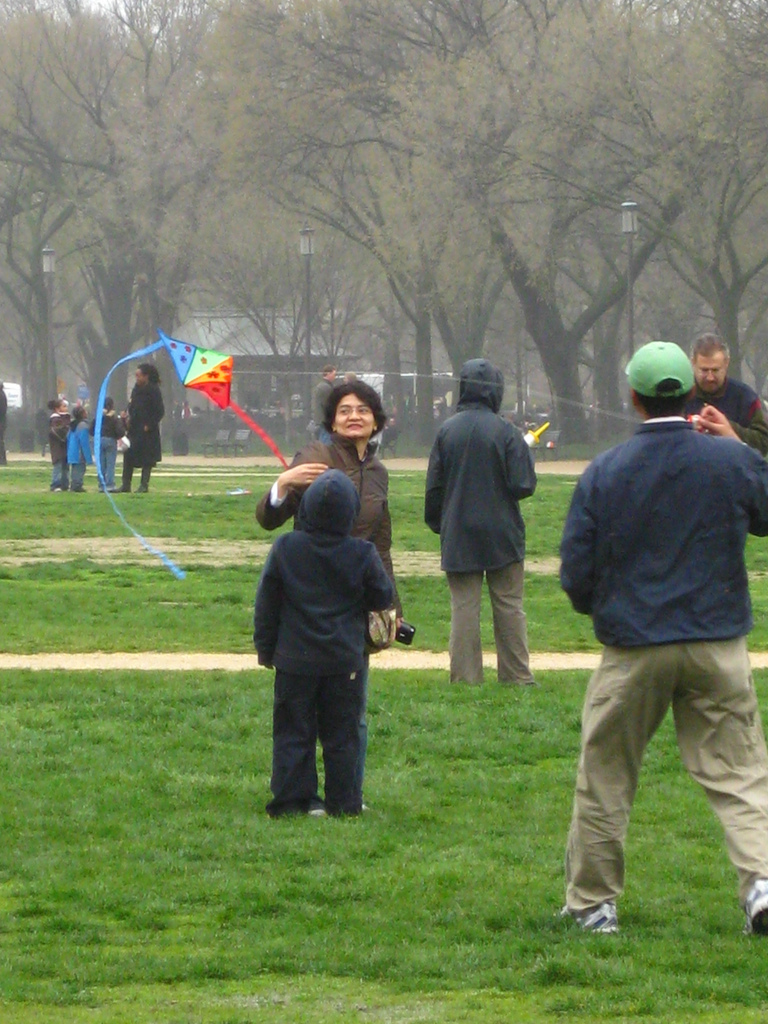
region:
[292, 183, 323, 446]
Tall street light in the park.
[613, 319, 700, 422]
Man wearing green ball cap.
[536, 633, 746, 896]
Man wearing tan pants.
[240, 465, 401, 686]
Young person wearing a blue jacket.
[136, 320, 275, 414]
A multi colored kite in the breeze.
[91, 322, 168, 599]
Bright blue tail of the kite.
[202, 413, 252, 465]
Bench across the park.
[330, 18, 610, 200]
Trees beginning to bud in the park.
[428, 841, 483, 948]
A person eating a orange.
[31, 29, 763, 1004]
people in a park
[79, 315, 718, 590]
kite on a string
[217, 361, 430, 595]
this is a woman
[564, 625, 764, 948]
man wearing khaki pants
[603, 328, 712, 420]
man wearing a green hat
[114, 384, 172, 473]
a black long coat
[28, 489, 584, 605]
a patch of dirt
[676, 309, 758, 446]
a man looking down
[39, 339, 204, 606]
tail of the kite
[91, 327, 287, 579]
a colorful kite flying in the air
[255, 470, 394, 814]
kid wearing a hooded jacket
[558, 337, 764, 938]
man with green cap flying a kite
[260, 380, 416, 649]
woman with brown hair holding a camera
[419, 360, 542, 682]
man wearing tan pants and a hooded raincoat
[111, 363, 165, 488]
woman wearing black raincoat with a black pony tail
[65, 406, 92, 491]
kid wearing a light blue coat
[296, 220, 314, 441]
a white streetlamp on a black metal pole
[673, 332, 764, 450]
man wearing a green and blue jacket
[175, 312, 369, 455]
a house behind a metal fence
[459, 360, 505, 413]
tan person has a head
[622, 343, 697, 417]
tan person has a head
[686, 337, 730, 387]
tan person has a head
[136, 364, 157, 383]
tan person has a head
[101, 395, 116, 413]
tan person has a head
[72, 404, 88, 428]
tan person has a head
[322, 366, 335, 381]
tan person has a head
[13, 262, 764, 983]
a group of people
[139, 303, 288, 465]
a multicolored low kite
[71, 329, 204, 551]
tail of the kite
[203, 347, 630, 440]
string on the kite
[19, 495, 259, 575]
patch on the dirt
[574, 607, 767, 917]
pair of khaki pants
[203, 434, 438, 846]
child in the grass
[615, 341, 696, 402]
a green baseball hat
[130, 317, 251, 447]
kite is in the air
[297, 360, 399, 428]
woman has black hair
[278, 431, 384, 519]
woman is wearing a jacket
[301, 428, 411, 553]
jacket is brown in coloe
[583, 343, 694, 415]
man is wearing a hat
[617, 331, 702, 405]
hat is green in color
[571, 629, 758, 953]
pants are tan in color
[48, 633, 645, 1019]
grass is green in color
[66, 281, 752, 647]
many people on grass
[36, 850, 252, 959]
grass under the people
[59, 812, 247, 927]
green grass on ground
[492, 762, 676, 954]
leg of the person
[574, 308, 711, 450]
green hat on person's head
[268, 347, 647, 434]
string in the air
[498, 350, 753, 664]
man with a jacket on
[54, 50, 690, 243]
many trees in the distance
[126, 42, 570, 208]
leaves on the tree